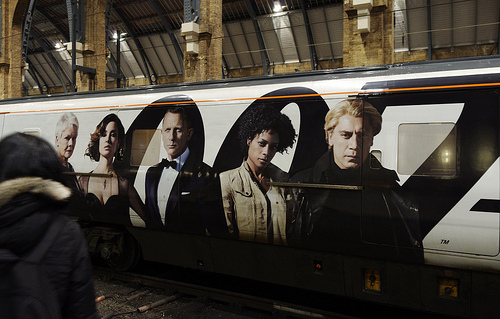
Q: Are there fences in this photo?
A: No, there are no fences.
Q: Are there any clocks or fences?
A: No, there are no fences or clocks.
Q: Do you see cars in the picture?
A: No, there are no cars.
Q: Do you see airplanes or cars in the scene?
A: No, there are no cars or airplanes.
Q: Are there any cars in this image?
A: No, there are no cars.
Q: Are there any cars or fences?
A: No, there are no cars or fences.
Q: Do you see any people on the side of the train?
A: Yes, there are people on the side of the train.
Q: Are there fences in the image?
A: No, there are no fences.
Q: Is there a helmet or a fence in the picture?
A: No, there are no fences or helmets.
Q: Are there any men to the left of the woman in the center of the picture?
A: Yes, there is a man to the left of the woman.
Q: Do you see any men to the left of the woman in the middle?
A: Yes, there is a man to the left of the woman.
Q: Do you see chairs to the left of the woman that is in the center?
A: No, there is a man to the left of the woman.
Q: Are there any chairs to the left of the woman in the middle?
A: No, there is a man to the left of the woman.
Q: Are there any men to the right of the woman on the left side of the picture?
A: Yes, there is a man to the right of the woman.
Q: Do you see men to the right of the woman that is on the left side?
A: Yes, there is a man to the right of the woman.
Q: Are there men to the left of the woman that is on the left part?
A: No, the man is to the right of the woman.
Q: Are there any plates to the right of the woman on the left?
A: No, there is a man to the right of the woman.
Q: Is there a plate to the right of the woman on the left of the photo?
A: No, there is a man to the right of the woman.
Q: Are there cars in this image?
A: No, there are no cars.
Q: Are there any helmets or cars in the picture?
A: No, there are no cars or helmets.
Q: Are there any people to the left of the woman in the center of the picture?
A: Yes, there is a person to the left of the woman.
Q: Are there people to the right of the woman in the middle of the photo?
A: No, the person is to the left of the woman.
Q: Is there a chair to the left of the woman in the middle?
A: No, there is a person to the left of the woman.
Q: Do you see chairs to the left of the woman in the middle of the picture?
A: No, there is a person to the left of the woman.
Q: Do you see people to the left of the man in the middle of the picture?
A: Yes, there is a person to the left of the man.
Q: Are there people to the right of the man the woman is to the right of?
A: No, the person is to the left of the man.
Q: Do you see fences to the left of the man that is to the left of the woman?
A: No, there is a person to the left of the man.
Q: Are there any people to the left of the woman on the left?
A: Yes, there is a person to the left of the woman.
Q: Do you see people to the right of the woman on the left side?
A: No, the person is to the left of the woman.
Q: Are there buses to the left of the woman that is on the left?
A: No, there is a person to the left of the woman.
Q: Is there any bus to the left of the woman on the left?
A: No, there is a person to the left of the woman.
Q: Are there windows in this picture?
A: Yes, there is a window.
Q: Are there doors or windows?
A: Yes, there is a window.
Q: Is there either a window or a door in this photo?
A: Yes, there is a window.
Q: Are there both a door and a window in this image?
A: No, there is a window but no doors.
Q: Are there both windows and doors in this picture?
A: No, there is a window but no doors.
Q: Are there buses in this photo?
A: No, there are no buses.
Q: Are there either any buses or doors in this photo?
A: No, there are no buses or doors.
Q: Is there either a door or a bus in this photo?
A: No, there are no buses or doors.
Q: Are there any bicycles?
A: No, there are no bicycles.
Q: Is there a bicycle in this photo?
A: No, there are no bicycles.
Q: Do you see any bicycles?
A: No, there are no bicycles.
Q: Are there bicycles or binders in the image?
A: No, there are no bicycles or binders.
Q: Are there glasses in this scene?
A: No, there are no glasses.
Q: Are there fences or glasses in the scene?
A: No, there are no glasses or fences.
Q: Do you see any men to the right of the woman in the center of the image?
A: Yes, there is a man to the right of the woman.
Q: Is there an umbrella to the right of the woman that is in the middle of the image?
A: No, there is a man to the right of the woman.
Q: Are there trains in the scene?
A: Yes, there is a train.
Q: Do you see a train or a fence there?
A: Yes, there is a train.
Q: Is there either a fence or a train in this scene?
A: Yes, there is a train.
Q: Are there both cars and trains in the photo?
A: No, there is a train but no cars.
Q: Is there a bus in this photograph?
A: No, there are no buses.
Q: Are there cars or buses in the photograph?
A: No, there are no buses or cars.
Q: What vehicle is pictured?
A: The vehicle is a train.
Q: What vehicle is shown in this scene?
A: The vehicle is a train.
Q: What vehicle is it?
A: The vehicle is a train.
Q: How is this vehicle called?
A: This is a train.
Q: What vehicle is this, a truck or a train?
A: This is a train.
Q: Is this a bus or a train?
A: This is a train.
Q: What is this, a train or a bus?
A: This is a train.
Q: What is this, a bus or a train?
A: This is a train.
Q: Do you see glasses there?
A: No, there are no glasses.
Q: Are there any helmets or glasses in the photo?
A: No, there are no glasses or helmets.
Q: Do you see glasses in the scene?
A: No, there are no glasses.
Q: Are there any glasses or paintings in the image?
A: No, there are no glasses or paintings.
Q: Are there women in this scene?
A: Yes, there is a woman.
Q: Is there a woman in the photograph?
A: Yes, there is a woman.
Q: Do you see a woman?
A: Yes, there is a woman.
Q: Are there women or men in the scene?
A: Yes, there is a woman.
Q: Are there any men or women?
A: Yes, there is a woman.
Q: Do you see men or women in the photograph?
A: Yes, there is a woman.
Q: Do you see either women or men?
A: Yes, there is a woman.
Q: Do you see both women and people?
A: Yes, there are both a woman and a person.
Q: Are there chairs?
A: No, there are no chairs.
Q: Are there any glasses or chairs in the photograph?
A: No, there are no chairs or glasses.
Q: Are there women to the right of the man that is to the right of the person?
A: Yes, there is a woman to the right of the man.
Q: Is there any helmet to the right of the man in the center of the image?
A: No, there is a woman to the right of the man.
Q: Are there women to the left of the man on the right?
A: Yes, there is a woman to the left of the man.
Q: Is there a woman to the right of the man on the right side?
A: No, the woman is to the left of the man.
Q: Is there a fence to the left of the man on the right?
A: No, there is a woman to the left of the man.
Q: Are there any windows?
A: Yes, there is a window.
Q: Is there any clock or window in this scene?
A: Yes, there is a window.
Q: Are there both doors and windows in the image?
A: No, there is a window but no doors.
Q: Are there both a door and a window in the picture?
A: No, there is a window but no doors.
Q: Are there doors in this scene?
A: No, there are no doors.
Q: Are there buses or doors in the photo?
A: No, there are no doors or buses.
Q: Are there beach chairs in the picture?
A: No, there are no beach chairs.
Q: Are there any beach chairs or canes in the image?
A: No, there are no beach chairs or canes.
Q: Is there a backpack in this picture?
A: Yes, there is a backpack.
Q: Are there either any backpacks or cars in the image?
A: Yes, there is a backpack.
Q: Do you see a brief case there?
A: No, there are no briefcases.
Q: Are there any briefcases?
A: No, there are no briefcases.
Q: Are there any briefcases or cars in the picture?
A: No, there are no briefcases or cars.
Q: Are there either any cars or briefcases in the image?
A: No, there are no briefcases or cars.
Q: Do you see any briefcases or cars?
A: No, there are no briefcases or cars.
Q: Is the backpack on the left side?
A: Yes, the backpack is on the left of the image.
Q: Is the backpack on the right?
A: No, the backpack is on the left of the image.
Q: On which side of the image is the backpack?
A: The backpack is on the left of the image.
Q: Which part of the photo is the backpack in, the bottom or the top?
A: The backpack is in the bottom of the image.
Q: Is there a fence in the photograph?
A: No, there are no fences.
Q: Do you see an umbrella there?
A: No, there are no umbrellas.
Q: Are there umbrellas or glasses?
A: No, there are no umbrellas or glasses.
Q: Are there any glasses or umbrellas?
A: No, there are no umbrellas or glasses.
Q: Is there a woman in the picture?
A: Yes, there is a woman.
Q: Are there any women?
A: Yes, there is a woman.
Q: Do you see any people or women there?
A: Yes, there is a woman.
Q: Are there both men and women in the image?
A: Yes, there are both a woman and a man.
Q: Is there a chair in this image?
A: No, there are no chairs.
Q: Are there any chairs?
A: No, there are no chairs.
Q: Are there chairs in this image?
A: No, there are no chairs.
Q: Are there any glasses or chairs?
A: No, there are no chairs or glasses.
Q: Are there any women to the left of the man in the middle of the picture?
A: Yes, there is a woman to the left of the man.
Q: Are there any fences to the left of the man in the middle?
A: No, there is a woman to the left of the man.